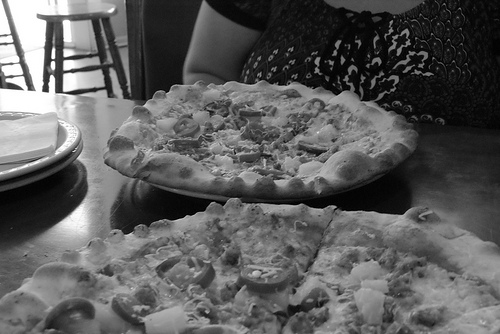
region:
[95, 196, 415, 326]
this is a pizza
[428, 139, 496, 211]
this is a table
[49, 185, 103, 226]
the table is wooden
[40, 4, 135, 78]
this is a stool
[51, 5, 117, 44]
the chair is wooden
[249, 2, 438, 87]
this is a lady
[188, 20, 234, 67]
the lady is light skinned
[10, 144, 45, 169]
this is a plate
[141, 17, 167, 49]
this is a wall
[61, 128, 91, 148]
the plate is white in color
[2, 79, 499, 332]
Pizzas on a table.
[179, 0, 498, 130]
Part of a lady.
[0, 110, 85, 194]
plates on a table.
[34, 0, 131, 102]
A wood bar stool.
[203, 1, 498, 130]
A ladies floral blouse.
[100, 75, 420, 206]
A pizza on a table.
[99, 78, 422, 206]
Pizza on a plate.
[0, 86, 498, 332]
Pizza on a table.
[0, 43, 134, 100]
Part of a kitchen floor.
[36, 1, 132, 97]
A stool in the kitchen.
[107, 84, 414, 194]
A pizza on a plate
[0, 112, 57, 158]
A napkin on a stack of plates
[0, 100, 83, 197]
A stack of plates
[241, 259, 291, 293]
A mushroom on a pizza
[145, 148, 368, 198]
The crust of the pizza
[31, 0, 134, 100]
A wooden stool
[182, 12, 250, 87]
A woman's arm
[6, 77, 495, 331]
Two pizzas on plates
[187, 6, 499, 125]
A woman sitting at the table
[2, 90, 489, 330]
A wooden table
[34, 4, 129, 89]
small round stool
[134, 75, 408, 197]
pizza pie on a plate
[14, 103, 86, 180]
napkins on top of plates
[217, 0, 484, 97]
person in a dark top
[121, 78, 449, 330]
two pizzas on a plate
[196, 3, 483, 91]
body of a woman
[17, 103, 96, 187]
two white plates on a table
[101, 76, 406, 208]
pizza on a table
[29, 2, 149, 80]
small stool in the background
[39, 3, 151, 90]
small wooden stool behind table